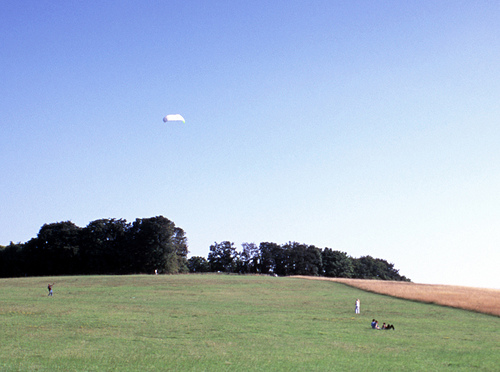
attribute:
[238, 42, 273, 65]
sky — blue, light, beautiful, nice, white, clear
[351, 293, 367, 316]
person — standing, flying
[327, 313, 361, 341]
grass — green, beautiful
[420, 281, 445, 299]
dirt — brown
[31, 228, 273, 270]
tree — group, green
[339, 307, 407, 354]
people — sitting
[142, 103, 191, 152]
parachute — white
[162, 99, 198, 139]
kite — flying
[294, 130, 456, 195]
streak — white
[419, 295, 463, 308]
line — black